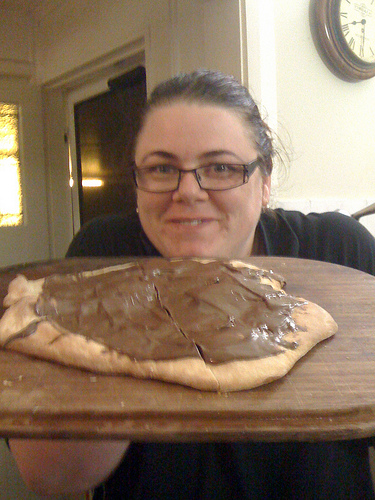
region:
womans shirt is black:
[115, 425, 367, 489]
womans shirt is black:
[136, 450, 344, 484]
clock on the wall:
[313, 0, 374, 86]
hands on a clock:
[339, 12, 372, 55]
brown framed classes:
[126, 154, 270, 196]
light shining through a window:
[0, 105, 36, 237]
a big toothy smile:
[161, 204, 224, 235]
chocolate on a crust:
[9, 269, 347, 366]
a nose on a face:
[167, 171, 215, 210]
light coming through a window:
[69, 98, 124, 193]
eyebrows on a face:
[193, 143, 247, 162]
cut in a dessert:
[121, 258, 260, 401]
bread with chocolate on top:
[6, 251, 349, 403]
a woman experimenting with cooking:
[40, 29, 338, 379]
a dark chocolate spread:
[107, 268, 226, 345]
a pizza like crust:
[2, 304, 188, 409]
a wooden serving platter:
[10, 254, 370, 458]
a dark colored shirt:
[61, 217, 373, 459]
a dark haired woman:
[114, 86, 296, 260]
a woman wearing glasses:
[122, 61, 296, 254]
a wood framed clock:
[299, 7, 372, 75]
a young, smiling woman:
[100, 47, 299, 269]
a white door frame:
[28, 42, 185, 291]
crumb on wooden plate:
[79, 362, 104, 382]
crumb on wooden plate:
[26, 364, 142, 405]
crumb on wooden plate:
[70, 360, 113, 401]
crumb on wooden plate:
[79, 369, 129, 412]